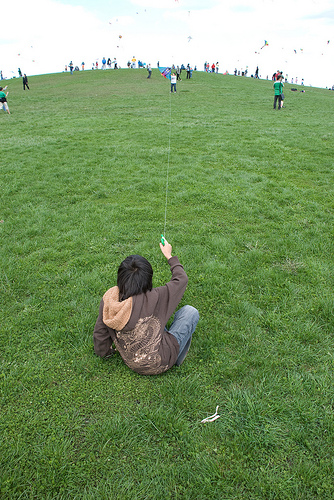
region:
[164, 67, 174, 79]
this is a kite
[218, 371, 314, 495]
this is a grass area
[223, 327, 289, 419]
the grass is green in color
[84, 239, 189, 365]
this is a boy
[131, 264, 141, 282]
this is the hair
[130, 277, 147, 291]
the hair is black in color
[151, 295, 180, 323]
this is a pullover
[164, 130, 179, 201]
this is a string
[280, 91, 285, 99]
this is a bag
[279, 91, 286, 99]
the bag is black in color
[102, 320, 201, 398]
boy sitting on the grass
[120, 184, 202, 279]
boy is holding kite string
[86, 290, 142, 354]
boy is wearing a brown jacket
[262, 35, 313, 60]
kites flying in the sky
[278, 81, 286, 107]
person carrying a bag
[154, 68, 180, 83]
person holding a kite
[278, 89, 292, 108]
child standing in front of person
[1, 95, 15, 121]
kid has a jacket tied at the waist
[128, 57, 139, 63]
person wearing a yellow shirt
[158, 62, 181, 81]
kite is red, blue and aqua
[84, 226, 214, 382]
person sitting on the grass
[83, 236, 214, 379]
person in a brown sweater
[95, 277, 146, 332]
hood of a sweater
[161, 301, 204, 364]
pair of blue jeans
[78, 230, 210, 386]
person with black hair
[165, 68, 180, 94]
person standing in the grass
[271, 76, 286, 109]
person standing in the grass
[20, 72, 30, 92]
person standing in the grass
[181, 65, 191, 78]
person standing in the grass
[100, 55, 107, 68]
person standing in the grass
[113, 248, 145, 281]
the boys black hair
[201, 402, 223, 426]
a white piece of string on the ground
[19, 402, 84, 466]
the green grass below the boy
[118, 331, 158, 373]
the dragon on the boys shirt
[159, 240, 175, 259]
the boys hand holding something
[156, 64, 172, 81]
the boys colorful kite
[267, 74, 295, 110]
a man wearing a green shirt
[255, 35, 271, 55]
a colorful kite in the sky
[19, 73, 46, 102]
a person wearing black in the background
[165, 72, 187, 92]
another boy in the background wearing a white shirt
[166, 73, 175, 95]
person standing on hill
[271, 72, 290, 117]
person standing on hill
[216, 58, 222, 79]
person standing on hill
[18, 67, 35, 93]
person standing on hill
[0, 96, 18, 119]
person standing on hill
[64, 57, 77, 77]
person standing on hill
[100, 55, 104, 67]
person standing on hill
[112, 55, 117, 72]
person standing on hill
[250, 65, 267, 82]
person standing on hill